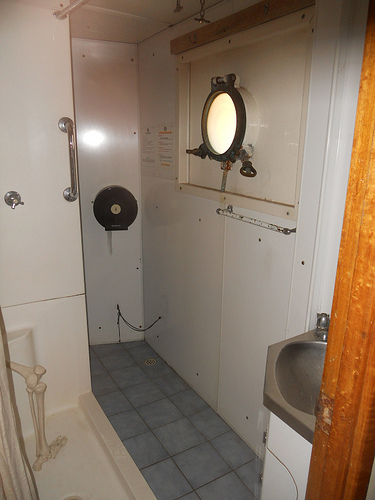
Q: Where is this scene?
A: In a boat.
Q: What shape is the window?
A: Round.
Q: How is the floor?
A: Tiled.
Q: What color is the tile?
A: Blue.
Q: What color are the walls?
A: White.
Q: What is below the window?
A: A towel rack.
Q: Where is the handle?
A: On the cabinet.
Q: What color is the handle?
A: Silver.